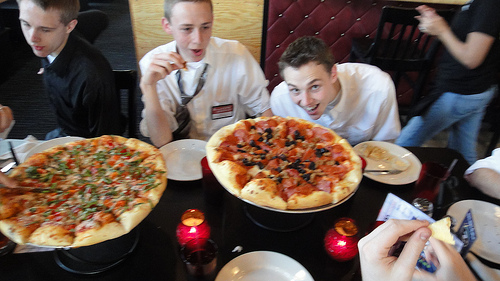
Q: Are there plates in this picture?
A: Yes, there is a plate.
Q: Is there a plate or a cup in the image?
A: Yes, there is a plate.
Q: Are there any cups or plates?
A: Yes, there is a plate.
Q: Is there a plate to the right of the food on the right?
A: Yes, there is a plate to the right of the food.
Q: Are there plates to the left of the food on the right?
A: No, the plate is to the right of the food.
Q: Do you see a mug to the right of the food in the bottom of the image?
A: No, there is a plate to the right of the food.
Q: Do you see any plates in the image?
A: Yes, there is a plate.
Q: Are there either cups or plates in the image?
A: Yes, there is a plate.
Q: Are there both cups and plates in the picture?
A: No, there is a plate but no cups.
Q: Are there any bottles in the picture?
A: No, there are no bottles.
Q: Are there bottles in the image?
A: No, there are no bottles.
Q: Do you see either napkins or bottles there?
A: No, there are no bottles or napkins.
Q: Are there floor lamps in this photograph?
A: No, there are no floor lamps.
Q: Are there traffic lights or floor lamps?
A: No, there are no floor lamps or traffic lights.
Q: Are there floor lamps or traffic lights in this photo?
A: No, there are no floor lamps or traffic lights.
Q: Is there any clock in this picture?
A: No, there are no clocks.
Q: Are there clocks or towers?
A: No, there are no clocks or towers.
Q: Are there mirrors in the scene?
A: No, there are no mirrors.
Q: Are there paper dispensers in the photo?
A: No, there are no paper dispensers.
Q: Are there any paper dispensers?
A: No, there are no paper dispensers.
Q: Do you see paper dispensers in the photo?
A: No, there are no paper dispensers.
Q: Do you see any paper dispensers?
A: No, there are no paper dispensers.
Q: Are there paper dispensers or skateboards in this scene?
A: No, there are no paper dispensers or skateboards.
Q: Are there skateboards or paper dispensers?
A: No, there are no paper dispensers or skateboards.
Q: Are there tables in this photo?
A: Yes, there is a table.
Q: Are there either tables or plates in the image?
A: Yes, there is a table.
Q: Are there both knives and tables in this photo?
A: No, there is a table but no knives.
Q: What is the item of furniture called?
A: The piece of furniture is a table.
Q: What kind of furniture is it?
A: The piece of furniture is a table.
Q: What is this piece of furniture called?
A: This is a table.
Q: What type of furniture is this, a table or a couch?
A: This is a table.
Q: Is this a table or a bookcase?
A: This is a table.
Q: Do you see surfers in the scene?
A: No, there are no surfers.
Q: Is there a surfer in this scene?
A: No, there are no surfers.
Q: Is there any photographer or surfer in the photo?
A: No, there are no surfers or photographers.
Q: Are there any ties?
A: Yes, there is a tie.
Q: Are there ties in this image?
A: Yes, there is a tie.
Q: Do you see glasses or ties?
A: Yes, there is a tie.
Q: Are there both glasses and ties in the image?
A: Yes, there are both a tie and glasses.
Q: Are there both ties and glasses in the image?
A: Yes, there are both a tie and glasses.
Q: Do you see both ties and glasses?
A: Yes, there are both a tie and glasses.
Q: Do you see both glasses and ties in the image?
A: Yes, there are both a tie and glasses.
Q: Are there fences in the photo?
A: No, there are no fences.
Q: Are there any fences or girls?
A: No, there are no fences or girls.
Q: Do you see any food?
A: Yes, there is food.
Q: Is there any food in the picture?
A: Yes, there is food.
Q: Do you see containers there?
A: No, there are no containers.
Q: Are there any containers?
A: No, there are no containers.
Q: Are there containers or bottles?
A: No, there are no containers or bottles.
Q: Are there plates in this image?
A: Yes, there is a plate.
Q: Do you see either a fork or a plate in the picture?
A: Yes, there is a plate.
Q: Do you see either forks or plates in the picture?
A: Yes, there is a plate.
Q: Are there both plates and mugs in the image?
A: No, there is a plate but no mugs.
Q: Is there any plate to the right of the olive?
A: Yes, there is a plate to the right of the olive.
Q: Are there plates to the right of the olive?
A: Yes, there is a plate to the right of the olive.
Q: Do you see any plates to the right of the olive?
A: Yes, there is a plate to the right of the olive.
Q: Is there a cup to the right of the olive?
A: No, there is a plate to the right of the olive.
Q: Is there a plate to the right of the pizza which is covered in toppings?
A: Yes, there is a plate to the right of the pizza.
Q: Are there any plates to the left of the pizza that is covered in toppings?
A: No, the plate is to the right of the pizza.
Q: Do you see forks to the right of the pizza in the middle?
A: No, there is a plate to the right of the pizza.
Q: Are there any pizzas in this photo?
A: Yes, there is a pizza.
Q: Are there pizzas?
A: Yes, there is a pizza.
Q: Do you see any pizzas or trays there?
A: Yes, there is a pizza.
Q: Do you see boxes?
A: No, there are no boxes.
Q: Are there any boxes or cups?
A: No, there are no boxes or cups.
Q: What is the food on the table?
A: The food is a pizza.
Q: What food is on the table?
A: The food is a pizza.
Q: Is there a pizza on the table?
A: Yes, there is a pizza on the table.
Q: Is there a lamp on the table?
A: No, there is a pizza on the table.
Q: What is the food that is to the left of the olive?
A: The food is a pizza.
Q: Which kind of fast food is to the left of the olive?
A: The food is a pizza.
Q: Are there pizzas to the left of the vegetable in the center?
A: Yes, there is a pizza to the left of the olive.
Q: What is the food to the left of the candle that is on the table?
A: The food is a pizza.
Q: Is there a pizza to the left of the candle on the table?
A: Yes, there is a pizza to the left of the candle.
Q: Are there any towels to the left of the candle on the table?
A: No, there is a pizza to the left of the candle.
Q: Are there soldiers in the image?
A: No, there are no soldiers.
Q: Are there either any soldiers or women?
A: No, there are no soldiers or women.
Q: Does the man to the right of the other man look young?
A: Yes, the man is young.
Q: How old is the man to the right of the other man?
A: The man is young.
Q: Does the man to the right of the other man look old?
A: No, the man is young.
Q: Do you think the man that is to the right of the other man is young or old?
A: The man is young.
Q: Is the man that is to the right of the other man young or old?
A: The man is young.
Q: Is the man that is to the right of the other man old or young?
A: The man is young.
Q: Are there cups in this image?
A: No, there are no cups.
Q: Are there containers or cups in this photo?
A: No, there are no cups or containers.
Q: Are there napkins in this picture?
A: No, there are no napkins.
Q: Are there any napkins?
A: No, there are no napkins.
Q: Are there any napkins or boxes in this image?
A: No, there are no napkins or boxes.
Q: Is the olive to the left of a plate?
A: Yes, the olive is to the left of a plate.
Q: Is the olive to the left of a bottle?
A: No, the olive is to the left of a plate.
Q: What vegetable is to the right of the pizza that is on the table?
A: The vegetable is an olive.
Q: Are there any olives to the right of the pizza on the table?
A: Yes, there is an olive to the right of the pizza.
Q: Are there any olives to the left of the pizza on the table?
A: No, the olive is to the right of the pizza.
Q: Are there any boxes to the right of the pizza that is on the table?
A: No, there is an olive to the right of the pizza.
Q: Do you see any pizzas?
A: Yes, there is a pizza.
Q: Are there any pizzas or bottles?
A: Yes, there is a pizza.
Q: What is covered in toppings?
A: The pizza is covered in toppings.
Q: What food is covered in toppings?
A: The food is a pizza.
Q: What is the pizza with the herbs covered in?
A: The pizza is covered in toppings.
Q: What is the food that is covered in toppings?
A: The food is a pizza.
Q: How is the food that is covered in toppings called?
A: The food is a pizza.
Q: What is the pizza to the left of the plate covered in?
A: The pizza is covered in toppings.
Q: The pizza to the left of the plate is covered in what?
A: The pizza is covered in toppings.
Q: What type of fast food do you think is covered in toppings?
A: The food is a pizza.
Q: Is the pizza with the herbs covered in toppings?
A: Yes, the pizza is covered in toppings.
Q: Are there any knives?
A: No, there are no knives.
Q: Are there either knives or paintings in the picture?
A: No, there are no knives or paintings.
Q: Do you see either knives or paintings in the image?
A: No, there are no knives or paintings.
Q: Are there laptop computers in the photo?
A: No, there are no laptop computers.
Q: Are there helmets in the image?
A: No, there are no helmets.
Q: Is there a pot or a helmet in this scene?
A: No, there are no helmets or pots.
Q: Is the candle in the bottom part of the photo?
A: Yes, the candle is in the bottom of the image.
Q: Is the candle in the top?
A: No, the candle is in the bottom of the image.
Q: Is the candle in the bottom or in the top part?
A: The candle is in the bottom of the image.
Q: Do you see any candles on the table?
A: Yes, there is a candle on the table.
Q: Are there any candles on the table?
A: Yes, there is a candle on the table.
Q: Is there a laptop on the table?
A: No, there is a candle on the table.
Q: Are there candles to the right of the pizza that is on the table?
A: Yes, there is a candle to the right of the pizza.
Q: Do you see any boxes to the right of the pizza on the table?
A: No, there is a candle to the right of the pizza.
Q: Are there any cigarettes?
A: No, there are no cigarettes.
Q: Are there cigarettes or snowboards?
A: No, there are no cigarettes or snowboards.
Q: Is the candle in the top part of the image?
A: No, the candle is in the bottom of the image.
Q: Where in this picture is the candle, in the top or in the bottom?
A: The candle is in the bottom of the image.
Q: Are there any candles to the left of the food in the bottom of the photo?
A: Yes, there is a candle to the left of the food.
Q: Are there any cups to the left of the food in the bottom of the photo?
A: No, there is a candle to the left of the food.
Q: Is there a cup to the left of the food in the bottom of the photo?
A: No, there is a candle to the left of the food.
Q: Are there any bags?
A: No, there are no bags.